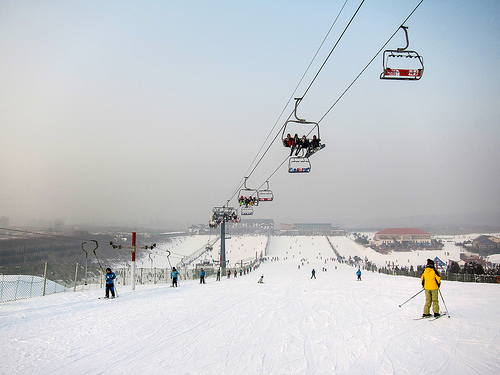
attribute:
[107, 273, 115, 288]
coat — blue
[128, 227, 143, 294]
pole — red and white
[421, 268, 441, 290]
sweater — yellow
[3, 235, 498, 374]
snow — smooth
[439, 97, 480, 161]
sky — cloudy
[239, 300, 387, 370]
snow — white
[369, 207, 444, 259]
large building — tan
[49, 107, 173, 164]
gray — empty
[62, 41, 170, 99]
sky — gray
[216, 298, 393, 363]
snow — white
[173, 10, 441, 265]
ski lift — empty, open air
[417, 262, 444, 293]
parka — yellow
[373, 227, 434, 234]
roof — red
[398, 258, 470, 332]
pole — extended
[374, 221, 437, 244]
building — distant